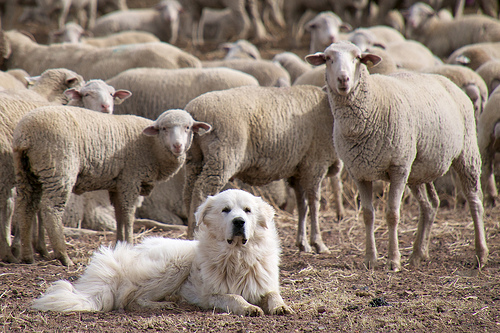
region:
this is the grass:
[311, 283, 361, 317]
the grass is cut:
[312, 281, 342, 310]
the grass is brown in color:
[296, 268, 348, 323]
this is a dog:
[49, 192, 286, 314]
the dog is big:
[38, 188, 298, 314]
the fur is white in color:
[171, 260, 198, 282]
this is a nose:
[232, 216, 246, 225]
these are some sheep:
[39, 13, 473, 188]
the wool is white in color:
[174, 4, 246, 42]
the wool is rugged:
[322, 155, 349, 167]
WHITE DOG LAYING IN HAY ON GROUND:
[24, 186, 291, 320]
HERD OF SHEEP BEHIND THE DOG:
[3, 7, 492, 268]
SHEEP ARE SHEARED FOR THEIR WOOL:
[322, 71, 493, 189]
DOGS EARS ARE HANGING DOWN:
[186, 200, 282, 232]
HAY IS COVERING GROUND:
[6, 229, 497, 331]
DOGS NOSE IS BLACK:
[221, 217, 253, 244]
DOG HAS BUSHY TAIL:
[27, 242, 130, 314]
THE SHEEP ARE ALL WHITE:
[3, 67, 485, 260]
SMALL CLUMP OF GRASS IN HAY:
[358, 287, 395, 312]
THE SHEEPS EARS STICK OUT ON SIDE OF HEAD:
[138, 116, 219, 144]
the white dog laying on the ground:
[42, 181, 302, 331]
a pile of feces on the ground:
[363, 287, 395, 318]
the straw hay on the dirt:
[279, 261, 497, 289]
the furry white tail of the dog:
[35, 244, 129, 324]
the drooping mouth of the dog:
[221, 218, 255, 248]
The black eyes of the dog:
[219, 203, 254, 217]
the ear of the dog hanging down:
[192, 194, 217, 232]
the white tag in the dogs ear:
[195, 124, 212, 141]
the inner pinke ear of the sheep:
[113, 87, 132, 100]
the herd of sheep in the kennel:
[27, 0, 499, 195]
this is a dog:
[111, 195, 329, 307]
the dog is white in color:
[146, 242, 219, 272]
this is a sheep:
[328, 50, 482, 329]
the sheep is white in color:
[399, 90, 455, 158]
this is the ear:
[136, 118, 162, 144]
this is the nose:
[223, 213, 253, 230]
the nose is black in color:
[231, 218, 249, 223]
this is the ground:
[323, 276, 437, 328]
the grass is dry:
[378, 265, 475, 330]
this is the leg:
[377, 172, 407, 272]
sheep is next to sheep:
[9, 104, 211, 262]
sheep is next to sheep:
[186, 85, 336, 256]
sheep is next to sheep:
[304, 38, 488, 270]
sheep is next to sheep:
[101, 67, 263, 118]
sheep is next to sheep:
[201, 58, 293, 87]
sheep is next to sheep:
[273, 11, 354, 82]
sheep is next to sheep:
[412, 67, 482, 112]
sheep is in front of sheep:
[308, 44, 491, 271]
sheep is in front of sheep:
[8, 109, 217, 277]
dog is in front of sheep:
[35, 186, 296, 317]